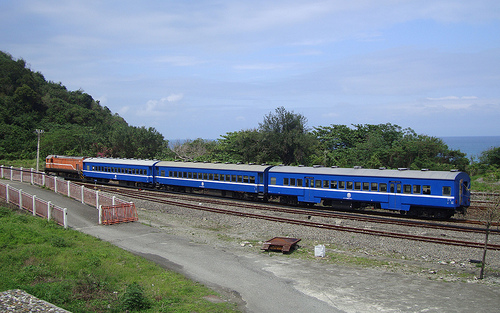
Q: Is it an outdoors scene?
A: Yes, it is outdoors.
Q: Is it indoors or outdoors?
A: It is outdoors.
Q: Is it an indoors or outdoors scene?
A: It is outdoors.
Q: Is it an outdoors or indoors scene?
A: It is outdoors.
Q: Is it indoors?
A: No, it is outdoors.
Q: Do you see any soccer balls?
A: No, there are no soccer balls.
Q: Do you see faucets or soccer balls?
A: No, there are no soccer balls or faucets.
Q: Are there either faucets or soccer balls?
A: No, there are no soccer balls or faucets.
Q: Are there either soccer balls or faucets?
A: No, there are no soccer balls or faucets.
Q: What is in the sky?
A: The clouds are in the sky.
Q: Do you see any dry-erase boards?
A: No, there are no dry-erase boards.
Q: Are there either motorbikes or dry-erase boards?
A: No, there are no dry-erase boards or motorbikes.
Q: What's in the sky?
A: The clouds are in the sky.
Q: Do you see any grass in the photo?
A: Yes, there is grass.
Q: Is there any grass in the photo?
A: Yes, there is grass.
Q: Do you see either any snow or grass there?
A: Yes, there is grass.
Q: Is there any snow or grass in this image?
A: Yes, there is grass.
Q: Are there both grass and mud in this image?
A: No, there is grass but no mud.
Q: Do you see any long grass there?
A: Yes, there is long grass.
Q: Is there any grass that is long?
A: Yes, there is grass that is long.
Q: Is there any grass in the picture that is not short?
A: Yes, there is long grass.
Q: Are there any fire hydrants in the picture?
A: No, there are no fire hydrants.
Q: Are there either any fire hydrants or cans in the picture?
A: No, there are no fire hydrants or cans.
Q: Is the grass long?
A: Yes, the grass is long.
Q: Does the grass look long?
A: Yes, the grass is long.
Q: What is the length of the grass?
A: The grass is long.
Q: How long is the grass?
A: The grass is long.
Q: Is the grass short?
A: No, the grass is long.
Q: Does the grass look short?
A: No, the grass is long.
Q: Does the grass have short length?
A: No, the grass is long.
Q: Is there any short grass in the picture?
A: No, there is grass but it is long.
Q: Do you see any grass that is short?
A: No, there is grass but it is long.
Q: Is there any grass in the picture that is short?
A: No, there is grass but it is long.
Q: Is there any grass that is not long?
A: No, there is grass but it is long.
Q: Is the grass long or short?
A: The grass is long.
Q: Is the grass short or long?
A: The grass is long.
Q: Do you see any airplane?
A: No, there are no airplanes.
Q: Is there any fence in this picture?
A: Yes, there is a fence.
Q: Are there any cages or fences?
A: Yes, there is a fence.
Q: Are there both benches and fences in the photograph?
A: No, there is a fence but no benches.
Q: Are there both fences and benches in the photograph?
A: No, there is a fence but no benches.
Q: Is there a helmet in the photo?
A: No, there are no helmets.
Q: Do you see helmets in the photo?
A: No, there are no helmets.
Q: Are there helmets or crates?
A: No, there are no helmets or crates.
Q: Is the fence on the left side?
A: Yes, the fence is on the left of the image.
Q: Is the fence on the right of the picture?
A: No, the fence is on the left of the image.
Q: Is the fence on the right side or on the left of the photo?
A: The fence is on the left of the image.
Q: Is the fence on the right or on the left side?
A: The fence is on the left of the image.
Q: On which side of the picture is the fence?
A: The fence is on the left of the image.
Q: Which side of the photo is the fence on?
A: The fence is on the left of the image.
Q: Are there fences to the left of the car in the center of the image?
A: Yes, there is a fence to the left of the car.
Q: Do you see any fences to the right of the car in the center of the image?
A: No, the fence is to the left of the car.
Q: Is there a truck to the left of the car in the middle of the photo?
A: No, there is a fence to the left of the car.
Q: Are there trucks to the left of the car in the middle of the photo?
A: No, there is a fence to the left of the car.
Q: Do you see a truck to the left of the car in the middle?
A: No, there is a fence to the left of the car.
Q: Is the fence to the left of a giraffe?
A: No, the fence is to the left of a car.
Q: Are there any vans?
A: No, there are no vans.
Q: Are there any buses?
A: No, there are no buses.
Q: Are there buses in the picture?
A: No, there are no buses.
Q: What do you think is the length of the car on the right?
A: The car is long.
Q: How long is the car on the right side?
A: The car is long.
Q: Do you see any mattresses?
A: No, there are no mattresses.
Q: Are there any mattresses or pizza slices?
A: No, there are no mattresses or pizza slices.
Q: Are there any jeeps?
A: No, there are no jeeps.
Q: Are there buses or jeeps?
A: No, there are no jeeps or buses.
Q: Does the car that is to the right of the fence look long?
A: Yes, the car is long.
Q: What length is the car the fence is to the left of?
A: The car is long.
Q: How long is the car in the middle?
A: The car is long.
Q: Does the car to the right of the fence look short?
A: No, the car is long.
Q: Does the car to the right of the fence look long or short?
A: The car is long.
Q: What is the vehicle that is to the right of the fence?
A: The vehicle is a car.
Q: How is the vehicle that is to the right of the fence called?
A: The vehicle is a car.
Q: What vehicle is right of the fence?
A: The vehicle is a car.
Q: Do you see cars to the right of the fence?
A: Yes, there is a car to the right of the fence.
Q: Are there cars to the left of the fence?
A: No, the car is to the right of the fence.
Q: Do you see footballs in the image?
A: No, there are no footballs.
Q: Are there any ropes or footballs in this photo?
A: No, there are no footballs or ropes.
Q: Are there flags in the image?
A: No, there are no flags.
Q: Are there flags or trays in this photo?
A: No, there are no flags or trays.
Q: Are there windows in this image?
A: Yes, there are windows.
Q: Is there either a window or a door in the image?
A: Yes, there are windows.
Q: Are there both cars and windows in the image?
A: Yes, there are both windows and a car.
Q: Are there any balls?
A: No, there are no balls.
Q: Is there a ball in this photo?
A: No, there are no balls.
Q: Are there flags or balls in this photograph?
A: No, there are no balls or flags.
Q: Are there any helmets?
A: No, there are no helmets.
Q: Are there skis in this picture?
A: No, there are no skis.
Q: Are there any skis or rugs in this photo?
A: No, there are no skis or rugs.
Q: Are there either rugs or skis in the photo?
A: No, there are no skis or rugs.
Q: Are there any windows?
A: Yes, there are windows.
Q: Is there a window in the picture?
A: Yes, there are windows.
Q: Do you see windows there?
A: Yes, there are windows.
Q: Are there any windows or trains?
A: Yes, there are windows.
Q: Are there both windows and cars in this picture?
A: Yes, there are both windows and a car.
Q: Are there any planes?
A: No, there are no planes.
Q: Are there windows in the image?
A: Yes, there are windows.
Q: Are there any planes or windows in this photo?
A: Yes, there are windows.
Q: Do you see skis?
A: No, there are no skis.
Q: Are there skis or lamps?
A: No, there are no skis or lamps.